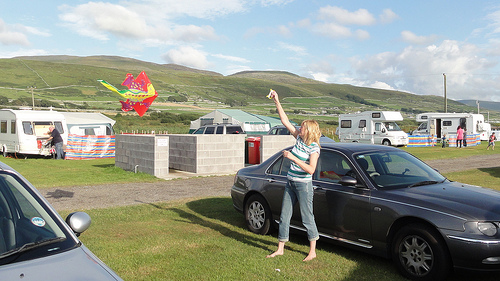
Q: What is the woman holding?
A: A kite string.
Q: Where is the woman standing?
A: Next to a car.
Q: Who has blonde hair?
A: A woman.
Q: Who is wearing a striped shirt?
A: A woman.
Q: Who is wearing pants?
A: A woman.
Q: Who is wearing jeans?
A: A woman.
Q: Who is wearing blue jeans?
A: A woman.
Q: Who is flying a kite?
A: Bare food blonde woman.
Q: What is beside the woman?
A: A black car.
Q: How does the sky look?
A: Blue with white clouds.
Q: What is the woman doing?
A: Flying a kite.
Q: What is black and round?
A: Tires.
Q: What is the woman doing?
A: Flying a kite.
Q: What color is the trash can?
A: Red.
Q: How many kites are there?
A: One.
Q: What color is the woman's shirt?
A: Green and white.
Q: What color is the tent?
A: White and green.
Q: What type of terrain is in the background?
A: Hills.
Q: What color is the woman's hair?
A: Blonde.